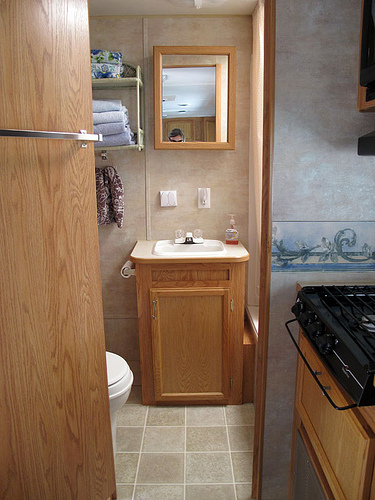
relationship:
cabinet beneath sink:
[131, 259, 245, 408] [150, 225, 229, 258]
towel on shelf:
[92, 96, 122, 112] [87, 143, 144, 153]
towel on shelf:
[92, 109, 128, 126] [87, 143, 144, 153]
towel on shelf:
[88, 119, 131, 135] [87, 143, 144, 153]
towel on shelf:
[95, 129, 135, 148] [87, 143, 144, 153]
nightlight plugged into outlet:
[197, 184, 209, 207] [196, 186, 212, 211]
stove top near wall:
[288, 277, 373, 412] [256, 42, 373, 496]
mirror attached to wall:
[148, 41, 235, 151] [86, 13, 249, 385]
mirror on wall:
[148, 41, 235, 151] [86, 13, 249, 385]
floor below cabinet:
[115, 402, 256, 498] [135, 236, 244, 406]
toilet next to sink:
[106, 347, 134, 459] [135, 227, 246, 409]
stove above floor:
[281, 279, 373, 414] [116, 383, 256, 499]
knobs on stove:
[286, 297, 336, 358] [289, 282, 373, 405]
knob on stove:
[312, 331, 334, 355] [289, 282, 373, 405]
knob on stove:
[302, 319, 323, 341] [289, 282, 373, 405]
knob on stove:
[295, 305, 312, 327] [289, 282, 373, 405]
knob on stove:
[290, 300, 305, 320] [289, 282, 373, 405]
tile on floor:
[182, 405, 227, 428] [114, 383, 254, 494]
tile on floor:
[183, 424, 228, 456] [114, 383, 254, 494]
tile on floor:
[180, 449, 233, 487] [114, 383, 254, 494]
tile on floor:
[137, 424, 187, 457] [114, 383, 254, 494]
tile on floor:
[132, 449, 187, 487] [114, 383, 254, 494]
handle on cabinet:
[146, 295, 158, 320] [127, 222, 251, 406]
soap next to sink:
[216, 209, 240, 247] [151, 227, 227, 259]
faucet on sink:
[169, 226, 207, 247] [151, 227, 227, 259]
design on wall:
[272, 218, 372, 277] [261, 104, 374, 498]